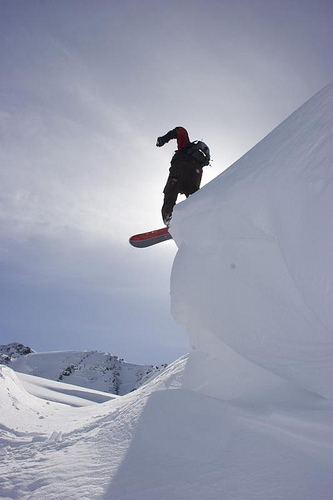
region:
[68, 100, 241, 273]
a snowboarder about to go off a cliff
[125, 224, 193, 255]
a red and grey snowboard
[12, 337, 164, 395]
low hills covered with snow in the distance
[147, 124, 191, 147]
the arm of the snowboarder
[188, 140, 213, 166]
a backpack that the snowboarder is wearing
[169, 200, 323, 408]
a very large snow drift that the snowboarder is on top of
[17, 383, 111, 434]
a small valley in the snow drifts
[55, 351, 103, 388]
a line of small trees on a distant hill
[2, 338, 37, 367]
a hill in the distance with foliage on it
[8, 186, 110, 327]
a white, blue and grey sky with clouds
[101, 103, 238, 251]
The person is performing a trick.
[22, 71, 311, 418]
A snowboarder.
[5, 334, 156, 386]
A mountain peak.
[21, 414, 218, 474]
The snow is white.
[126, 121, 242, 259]
The snowboarder has a backpack on.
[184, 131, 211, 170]
The backpack is black and grey.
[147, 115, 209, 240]
The snowboarder is wearing a red and black jacket.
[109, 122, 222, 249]
The person is wearing black snow pants.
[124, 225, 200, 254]
The snowboard is black and red.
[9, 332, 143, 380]
Rock is showing through the snow.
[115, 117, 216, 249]
snowboarder on ledge of mountain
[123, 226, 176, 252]
short red snowboard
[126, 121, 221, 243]
snowboarder wearing snow helmet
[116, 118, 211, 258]
snowboarder in mid air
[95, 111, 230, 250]
snowboarder wearing snow goggles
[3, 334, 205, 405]
snow covered mountains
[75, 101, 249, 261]
snowboarder with red sleeves and black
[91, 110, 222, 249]
snowboarder performing a trick in air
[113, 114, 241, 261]
snowboarder surrounded by snow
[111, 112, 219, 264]
snowboarder with elbow in air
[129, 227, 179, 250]
red and grey snow board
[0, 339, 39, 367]
mountain top in the distance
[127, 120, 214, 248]
the view of a skateboarder from below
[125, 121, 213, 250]
snowboarder is coming down a hill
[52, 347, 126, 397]
trees on a distant mountain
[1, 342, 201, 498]
bright white snow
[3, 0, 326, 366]
clear sky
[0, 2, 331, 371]
a cloudless sky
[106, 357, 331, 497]
a shadow cast by the hill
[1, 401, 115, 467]
tracks in the snow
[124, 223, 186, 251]
red and gray snowboard perched on the edge of a snow bank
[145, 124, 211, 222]
man skiing off the top of a snowy hill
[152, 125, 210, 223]
professional snowboarder jumping off a snowbank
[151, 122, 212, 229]
novice learning to ski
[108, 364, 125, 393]
a path of black rock along a snow hill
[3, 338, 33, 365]
a snow covered mountain under a clear sky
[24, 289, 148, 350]
a bright blue sky above the mountains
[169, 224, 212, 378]
a steep snow bank supporting a skier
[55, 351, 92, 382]
a trail of large boulders on a snowy mountain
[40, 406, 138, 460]
the sun reflecting on the white snow